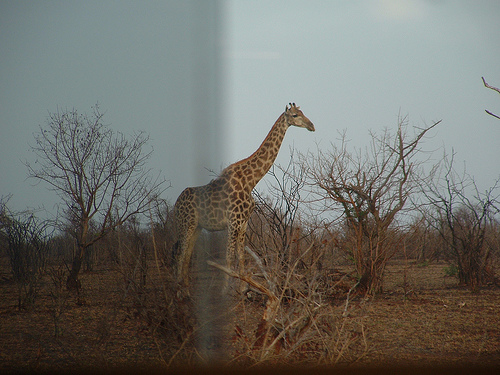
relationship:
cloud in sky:
[0, 0, 500, 102] [171, 8, 449, 173]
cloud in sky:
[0, 0, 500, 102] [3, 2, 498, 246]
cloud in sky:
[0, 0, 500, 102] [245, 14, 493, 131]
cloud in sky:
[0, 0, 500, 102] [4, 4, 496, 43]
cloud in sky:
[0, 0, 500, 102] [9, 4, 495, 80]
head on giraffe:
[279, 99, 319, 136] [165, 95, 318, 303]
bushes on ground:
[320, 216, 402, 297] [26, 306, 496, 371]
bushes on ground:
[2, 213, 56, 313] [26, 306, 496, 371]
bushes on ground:
[201, 240, 363, 370] [26, 306, 496, 371]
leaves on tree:
[343, 145, 390, 162] [33, 82, 151, 333]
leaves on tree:
[343, 145, 390, 162] [306, 89, 440, 293]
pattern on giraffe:
[211, 165, 254, 221] [165, 95, 318, 303]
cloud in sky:
[224, 44, 308, 74] [3, 2, 498, 246]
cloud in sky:
[0, 0, 500, 102] [9, 15, 495, 55]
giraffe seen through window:
[165, 95, 318, 303] [9, 4, 243, 368]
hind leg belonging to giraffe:
[190, 222, 201, 292] [153, 89, 327, 325]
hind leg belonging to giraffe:
[153, 222, 183, 320] [153, 89, 327, 325]